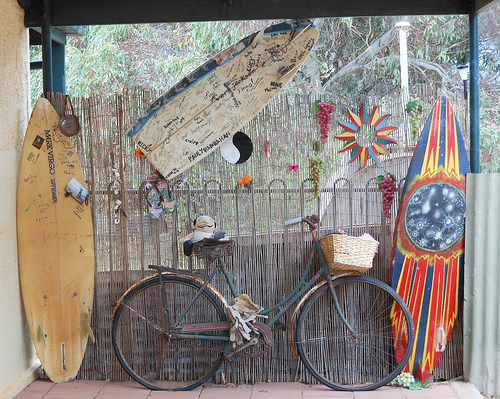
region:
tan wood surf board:
[16, 98, 96, 383]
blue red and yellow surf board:
[391, 94, 465, 384]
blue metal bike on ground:
[113, 217, 415, 389]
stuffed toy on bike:
[179, 213, 231, 251]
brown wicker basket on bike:
[323, 232, 378, 272]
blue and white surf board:
[128, 18, 323, 177]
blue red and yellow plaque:
[339, 103, 396, 163]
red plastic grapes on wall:
[313, 98, 334, 140]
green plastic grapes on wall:
[310, 155, 322, 195]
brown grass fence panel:
[43, 92, 472, 382]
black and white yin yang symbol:
[218, 131, 255, 167]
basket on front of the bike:
[315, 225, 380, 278]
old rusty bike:
[106, 223, 421, 394]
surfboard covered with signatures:
[123, 18, 319, 181]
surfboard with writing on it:
[11, 80, 96, 387]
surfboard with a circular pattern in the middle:
[382, 88, 475, 387]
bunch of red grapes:
[311, 95, 334, 142]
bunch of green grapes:
[300, 158, 326, 199]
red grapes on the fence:
[375, 173, 398, 223]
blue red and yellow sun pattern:
[331, 100, 403, 172]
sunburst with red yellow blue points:
[331, 103, 403, 173]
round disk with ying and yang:
[219, 130, 255, 167]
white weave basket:
[319, 223, 382, 276]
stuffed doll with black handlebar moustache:
[186, 213, 223, 243]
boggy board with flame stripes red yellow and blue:
[387, 99, 468, 375]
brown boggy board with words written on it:
[14, 94, 104, 381]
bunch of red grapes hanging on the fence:
[378, 171, 399, 219]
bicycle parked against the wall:
[108, 221, 407, 393]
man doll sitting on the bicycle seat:
[176, 211, 236, 261]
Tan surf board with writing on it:
[16, 96, 96, 381]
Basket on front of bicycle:
[321, 229, 379, 273]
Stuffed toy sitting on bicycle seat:
[178, 212, 234, 256]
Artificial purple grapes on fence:
[373, 171, 396, 220]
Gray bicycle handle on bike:
[281, 215, 304, 227]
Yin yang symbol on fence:
[218, 128, 254, 165]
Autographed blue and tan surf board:
[126, 15, 317, 180]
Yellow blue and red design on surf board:
[417, 97, 467, 172]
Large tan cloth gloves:
[224, 290, 269, 345]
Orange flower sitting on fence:
[236, 170, 253, 187]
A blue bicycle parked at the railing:
[110, 213, 415, 389]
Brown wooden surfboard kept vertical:
[15, 98, 95, 381]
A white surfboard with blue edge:
[125, 18, 320, 182]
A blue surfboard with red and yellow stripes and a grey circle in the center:
[389, 95, 479, 385]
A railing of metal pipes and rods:
[87, 178, 403, 380]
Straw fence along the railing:
[35, 89, 465, 380]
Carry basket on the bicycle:
[320, 234, 378, 271]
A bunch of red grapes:
[317, 99, 334, 144]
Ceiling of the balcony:
[25, 0, 499, 23]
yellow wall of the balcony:
[0, 2, 40, 397]